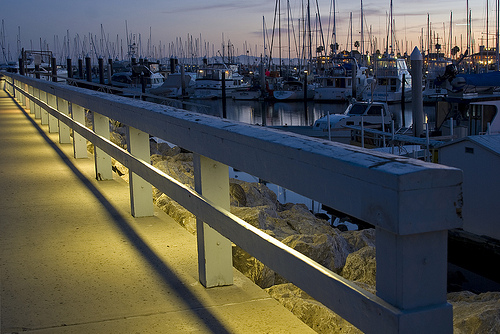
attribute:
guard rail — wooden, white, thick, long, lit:
[4, 65, 465, 333]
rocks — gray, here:
[229, 173, 357, 297]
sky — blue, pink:
[5, 4, 496, 53]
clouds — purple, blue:
[255, 7, 385, 46]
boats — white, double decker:
[52, 48, 493, 224]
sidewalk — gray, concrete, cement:
[3, 92, 313, 333]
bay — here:
[36, 50, 499, 220]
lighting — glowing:
[16, 86, 136, 183]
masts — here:
[27, 7, 491, 64]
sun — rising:
[436, 11, 494, 45]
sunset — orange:
[302, 11, 498, 51]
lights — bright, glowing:
[316, 53, 498, 75]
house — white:
[418, 122, 499, 277]